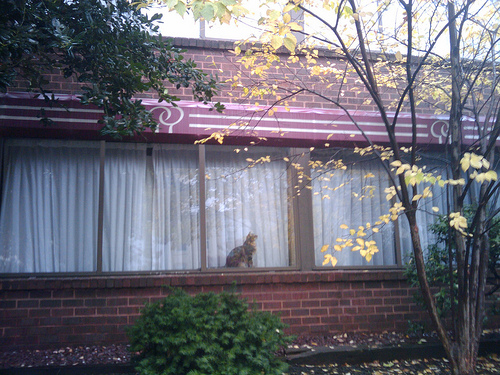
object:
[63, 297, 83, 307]
red bricks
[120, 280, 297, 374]
bush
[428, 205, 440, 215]
leaf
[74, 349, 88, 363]
leaf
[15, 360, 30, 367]
leaf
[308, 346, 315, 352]
leaf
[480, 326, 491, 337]
leaf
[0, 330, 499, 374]
sidewalk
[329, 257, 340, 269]
leaves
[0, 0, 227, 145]
tree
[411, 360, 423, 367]
leaves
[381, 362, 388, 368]
leaves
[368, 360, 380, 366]
leaves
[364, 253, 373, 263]
leaves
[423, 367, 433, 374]
leaves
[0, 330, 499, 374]
ground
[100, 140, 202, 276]
window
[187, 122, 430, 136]
line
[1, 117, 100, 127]
line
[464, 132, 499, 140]
line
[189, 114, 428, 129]
stripe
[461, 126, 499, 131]
stripe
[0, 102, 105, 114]
stripe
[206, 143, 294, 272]
window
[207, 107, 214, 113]
leaves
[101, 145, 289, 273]
curtain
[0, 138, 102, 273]
curtain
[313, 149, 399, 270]
windows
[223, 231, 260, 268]
cat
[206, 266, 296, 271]
window sill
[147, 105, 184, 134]
design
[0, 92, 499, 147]
roof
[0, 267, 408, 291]
brick border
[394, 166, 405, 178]
leaves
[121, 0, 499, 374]
tree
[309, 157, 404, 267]
curtains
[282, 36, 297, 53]
leaves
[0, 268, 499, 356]
wall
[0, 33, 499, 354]
building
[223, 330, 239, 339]
leaves